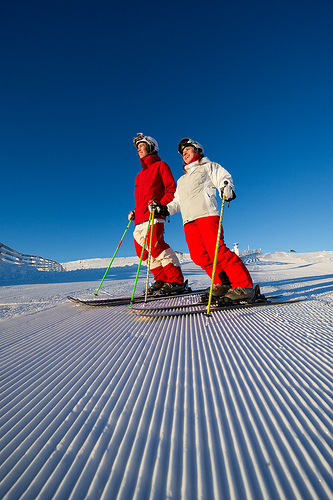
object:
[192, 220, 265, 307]
pants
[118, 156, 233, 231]
jacket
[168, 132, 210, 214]
girl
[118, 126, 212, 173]
helmet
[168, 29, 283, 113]
sky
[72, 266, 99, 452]
lines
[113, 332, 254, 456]
ground